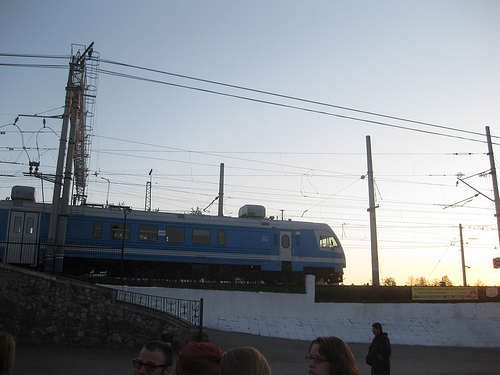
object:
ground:
[333, 346, 412, 360]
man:
[365, 320, 392, 373]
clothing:
[365, 331, 391, 369]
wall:
[116, 286, 499, 350]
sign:
[411, 287, 479, 301]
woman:
[305, 335, 362, 375]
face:
[370, 325, 378, 335]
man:
[137, 339, 174, 374]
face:
[138, 347, 160, 372]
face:
[307, 343, 324, 374]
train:
[0, 186, 346, 285]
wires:
[90, 93, 326, 205]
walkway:
[14, 322, 498, 372]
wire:
[2, 54, 72, 60]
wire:
[5, 63, 69, 69]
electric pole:
[365, 136, 380, 283]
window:
[192, 227, 212, 246]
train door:
[7, 209, 42, 264]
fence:
[117, 288, 204, 336]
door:
[278, 228, 293, 261]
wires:
[4, 136, 46, 180]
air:
[0, 0, 499, 375]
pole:
[217, 163, 225, 217]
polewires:
[368, 171, 458, 266]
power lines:
[309, 100, 386, 126]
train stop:
[0, 273, 204, 371]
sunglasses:
[135, 360, 156, 372]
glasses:
[303, 353, 324, 364]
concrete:
[314, 285, 484, 303]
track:
[104, 273, 479, 303]